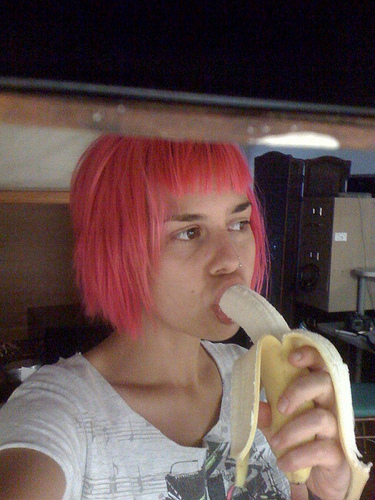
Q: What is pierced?
A: The woman's nose.